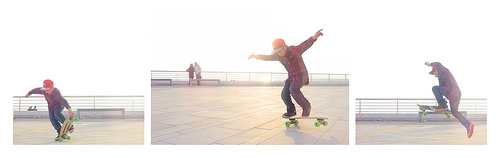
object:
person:
[193, 62, 202, 87]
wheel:
[67, 120, 71, 124]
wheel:
[58, 138, 63, 142]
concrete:
[13, 119, 145, 143]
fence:
[355, 96, 488, 123]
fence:
[150, 70, 347, 84]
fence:
[14, 95, 146, 116]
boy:
[425, 61, 475, 138]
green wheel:
[314, 122, 321, 128]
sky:
[17, 6, 144, 95]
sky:
[152, 0, 348, 68]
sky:
[354, 15, 489, 97]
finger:
[317, 29, 324, 33]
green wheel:
[285, 121, 290, 126]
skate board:
[285, 117, 328, 127]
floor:
[153, 86, 346, 145]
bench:
[418, 111, 468, 123]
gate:
[355, 100, 487, 118]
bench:
[75, 108, 126, 119]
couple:
[185, 62, 202, 87]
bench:
[150, 79, 172, 86]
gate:
[153, 71, 350, 89]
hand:
[248, 53, 259, 61]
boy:
[24, 79, 77, 141]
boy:
[247, 29, 325, 117]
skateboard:
[56, 116, 79, 142]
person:
[186, 63, 195, 86]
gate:
[12, 95, 145, 112]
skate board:
[412, 103, 452, 119]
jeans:
[279, 79, 313, 113]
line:
[13, 114, 53, 143]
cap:
[271, 38, 286, 54]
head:
[271, 39, 288, 58]